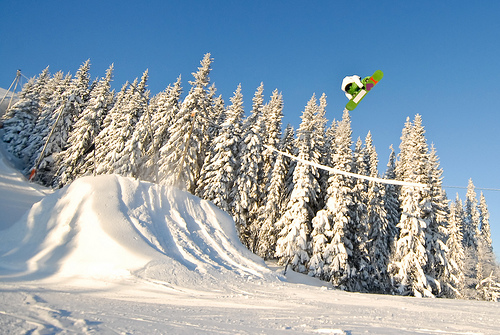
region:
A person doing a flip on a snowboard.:
[337, 68, 390, 113]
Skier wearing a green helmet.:
[343, 81, 363, 97]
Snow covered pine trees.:
[0, 67, 497, 304]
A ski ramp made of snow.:
[0, 163, 265, 295]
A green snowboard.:
[345, 69, 390, 113]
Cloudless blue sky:
[2, 0, 499, 237]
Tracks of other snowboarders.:
[106, 170, 296, 295]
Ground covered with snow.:
[2, 171, 497, 333]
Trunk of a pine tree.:
[279, 254, 300, 279]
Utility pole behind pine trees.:
[4, 65, 31, 127]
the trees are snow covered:
[202, 95, 452, 272]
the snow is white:
[210, 98, 447, 293]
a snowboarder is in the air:
[276, 34, 414, 144]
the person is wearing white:
[317, 60, 373, 115]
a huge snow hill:
[65, 140, 321, 310]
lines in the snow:
[149, 177, 281, 291]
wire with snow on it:
[265, 135, 487, 215]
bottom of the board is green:
[347, 67, 388, 114]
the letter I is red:
[367, 71, 382, 85]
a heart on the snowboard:
[357, 77, 377, 97]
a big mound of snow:
[11, 163, 303, 307]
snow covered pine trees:
[14, 50, 351, 265]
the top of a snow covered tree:
[191, 48, 218, 91]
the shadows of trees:
[0, 162, 84, 281]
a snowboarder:
[331, 57, 381, 114]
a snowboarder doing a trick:
[330, 61, 387, 121]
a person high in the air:
[337, 70, 373, 100]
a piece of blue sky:
[268, 34, 435, 66]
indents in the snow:
[115, 174, 275, 294]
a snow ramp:
[28, 163, 305, 295]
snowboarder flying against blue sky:
[325, 56, 385, 117]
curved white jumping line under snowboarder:
[247, 60, 437, 190]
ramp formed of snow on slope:
[5, 152, 355, 309]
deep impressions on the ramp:
[117, 180, 252, 281]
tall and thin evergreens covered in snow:
[65, 66, 435, 271]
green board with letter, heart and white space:
[332, 57, 383, 112]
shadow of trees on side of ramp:
[15, 190, 85, 282]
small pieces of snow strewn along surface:
[150, 286, 482, 326]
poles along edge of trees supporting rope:
[10, 45, 490, 281]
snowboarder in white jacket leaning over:
[339, 68, 376, 111]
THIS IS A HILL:
[14, 168, 274, 303]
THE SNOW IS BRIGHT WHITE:
[1, 148, 493, 333]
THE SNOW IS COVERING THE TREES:
[5, 36, 499, 303]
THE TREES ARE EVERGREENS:
[1, 49, 498, 301]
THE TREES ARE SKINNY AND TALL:
[3, 53, 497, 301]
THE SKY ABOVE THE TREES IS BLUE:
[1, 0, 498, 269]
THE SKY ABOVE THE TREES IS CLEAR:
[0, 0, 499, 195]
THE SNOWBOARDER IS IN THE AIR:
[337, 66, 386, 116]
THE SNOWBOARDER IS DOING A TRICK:
[338, 65, 385, 115]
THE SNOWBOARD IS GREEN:
[343, 63, 400, 113]